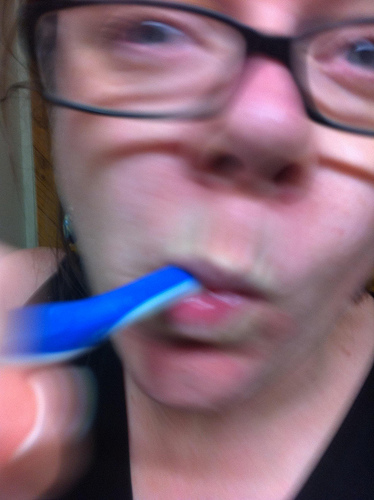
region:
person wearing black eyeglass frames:
[15, 2, 365, 149]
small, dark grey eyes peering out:
[95, 12, 367, 64]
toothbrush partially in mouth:
[4, 226, 256, 380]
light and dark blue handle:
[3, 250, 202, 374]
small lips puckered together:
[127, 229, 286, 357]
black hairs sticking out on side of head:
[7, 15, 82, 275]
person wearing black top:
[20, 254, 366, 486]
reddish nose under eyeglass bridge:
[166, 30, 333, 134]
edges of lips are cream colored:
[134, 212, 292, 367]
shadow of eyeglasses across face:
[53, 70, 369, 190]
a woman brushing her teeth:
[1, 2, 371, 498]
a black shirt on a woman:
[50, 335, 372, 498]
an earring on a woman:
[56, 210, 93, 251]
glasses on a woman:
[18, 1, 370, 124]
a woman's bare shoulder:
[0, 235, 68, 291]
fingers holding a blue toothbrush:
[2, 255, 206, 364]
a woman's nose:
[215, 61, 316, 184]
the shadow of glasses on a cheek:
[83, 127, 196, 180]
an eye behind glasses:
[100, 10, 191, 46]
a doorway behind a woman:
[11, 41, 74, 247]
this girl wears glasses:
[20, 4, 372, 117]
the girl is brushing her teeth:
[8, 229, 364, 414]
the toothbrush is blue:
[4, 233, 215, 368]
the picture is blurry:
[13, 9, 360, 390]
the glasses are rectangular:
[14, 2, 371, 112]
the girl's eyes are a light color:
[119, 15, 181, 59]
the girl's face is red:
[43, 6, 349, 491]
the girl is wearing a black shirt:
[15, 264, 351, 498]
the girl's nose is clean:
[191, 125, 328, 206]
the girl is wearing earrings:
[55, 204, 80, 253]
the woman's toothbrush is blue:
[0, 247, 214, 347]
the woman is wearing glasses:
[10, 2, 367, 156]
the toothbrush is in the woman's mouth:
[21, 217, 279, 398]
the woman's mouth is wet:
[115, 246, 263, 353]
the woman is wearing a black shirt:
[17, 235, 355, 486]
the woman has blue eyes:
[91, 4, 367, 76]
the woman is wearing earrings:
[30, 206, 134, 274]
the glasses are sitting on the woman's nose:
[20, 1, 343, 168]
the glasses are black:
[13, 1, 368, 162]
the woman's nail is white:
[12, 382, 61, 461]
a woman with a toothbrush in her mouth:
[0, 1, 371, 496]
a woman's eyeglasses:
[28, 3, 371, 125]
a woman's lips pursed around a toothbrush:
[163, 253, 247, 333]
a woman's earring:
[59, 210, 70, 238]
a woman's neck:
[129, 399, 303, 493]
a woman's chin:
[131, 356, 257, 411]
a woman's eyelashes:
[99, 13, 135, 38]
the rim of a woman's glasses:
[42, 87, 209, 119]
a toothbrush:
[0, 265, 177, 369]